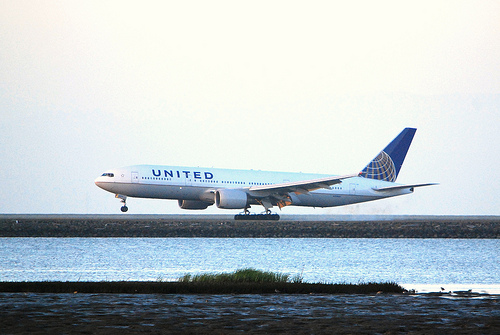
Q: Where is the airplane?
A: On the ground.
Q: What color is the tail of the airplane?
A: Blue.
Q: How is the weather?
A: Overcast.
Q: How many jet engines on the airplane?
A: Two.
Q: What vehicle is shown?
A: An airplane.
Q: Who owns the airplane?
A: United.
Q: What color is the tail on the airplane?
A: Blue.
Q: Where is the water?
A: In front of the runway.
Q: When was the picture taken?
A: During the daytime.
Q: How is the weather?
A: Overcast.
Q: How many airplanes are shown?
A: One.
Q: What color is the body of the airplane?
A: White.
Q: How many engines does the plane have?
A: The plane has two engines.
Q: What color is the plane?
A: The plane is blue and white.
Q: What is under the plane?
A: Low brown and green grasses.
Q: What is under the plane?
A: A flat rocky landscape.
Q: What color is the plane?
A: A white airplane with blue and orange markings.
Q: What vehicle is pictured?
A: Plane.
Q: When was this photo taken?
A: Daytime.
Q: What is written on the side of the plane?
A: United.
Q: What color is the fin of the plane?
A: Blue.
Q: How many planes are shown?
A: 1.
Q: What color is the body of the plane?
A: White.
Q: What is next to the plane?
A: Water.